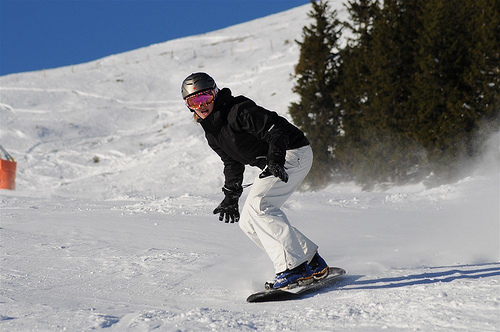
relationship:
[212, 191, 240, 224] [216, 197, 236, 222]
glove on hand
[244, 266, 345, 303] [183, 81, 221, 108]
snowboard wearing goggles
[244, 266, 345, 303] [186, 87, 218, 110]
snowboard wearing goggles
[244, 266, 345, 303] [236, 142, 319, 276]
snowboard wearing pants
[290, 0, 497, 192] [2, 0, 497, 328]
bush on slope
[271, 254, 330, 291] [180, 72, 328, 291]
feet of lady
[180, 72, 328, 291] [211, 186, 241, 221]
lady wearing a glove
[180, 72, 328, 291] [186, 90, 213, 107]
lady wearing snow goggles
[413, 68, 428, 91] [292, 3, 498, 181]
green leaves on tree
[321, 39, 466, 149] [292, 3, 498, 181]
green leaves on tree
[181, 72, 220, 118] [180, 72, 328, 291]
head of lady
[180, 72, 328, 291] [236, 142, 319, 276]
lady wearing pants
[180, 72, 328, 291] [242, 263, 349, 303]
lady on a snow board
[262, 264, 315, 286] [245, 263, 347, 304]
boot on a snowboard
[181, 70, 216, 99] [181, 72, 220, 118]
helmet on a womans head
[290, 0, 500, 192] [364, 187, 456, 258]
bush in snow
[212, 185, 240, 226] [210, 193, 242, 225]
glove on a womans hand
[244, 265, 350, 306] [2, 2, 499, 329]
snowboard on snow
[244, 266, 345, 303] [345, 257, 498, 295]
snowboard has shadow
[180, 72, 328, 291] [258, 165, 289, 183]
lady has hand